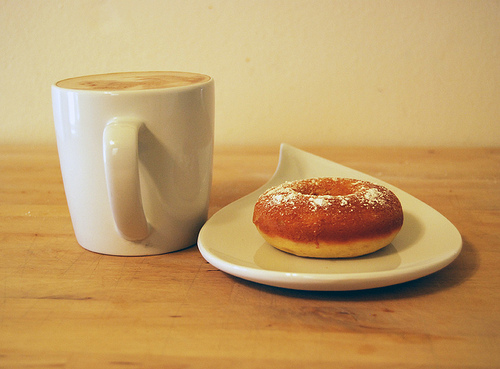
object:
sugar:
[254, 177, 397, 210]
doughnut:
[251, 175, 406, 262]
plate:
[196, 140, 466, 294]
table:
[1, 144, 500, 368]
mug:
[49, 69, 217, 258]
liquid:
[50, 70, 213, 92]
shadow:
[253, 236, 402, 274]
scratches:
[10, 256, 203, 358]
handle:
[101, 118, 164, 245]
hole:
[294, 182, 359, 198]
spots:
[168, 314, 181, 320]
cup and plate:
[52, 69, 465, 293]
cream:
[57, 71, 145, 90]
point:
[274, 141, 311, 159]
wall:
[1, 0, 499, 144]